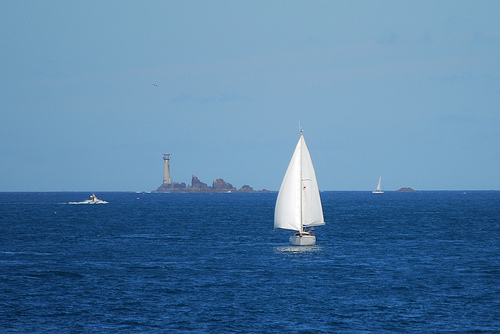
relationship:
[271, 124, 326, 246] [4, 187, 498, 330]
boat in water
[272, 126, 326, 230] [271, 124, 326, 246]
sail on boat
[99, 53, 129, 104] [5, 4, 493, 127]
white clouds in sky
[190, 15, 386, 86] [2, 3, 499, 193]
clouds in sky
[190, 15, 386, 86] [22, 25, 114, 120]
clouds in sky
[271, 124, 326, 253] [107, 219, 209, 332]
boat on water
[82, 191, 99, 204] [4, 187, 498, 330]
jetski on water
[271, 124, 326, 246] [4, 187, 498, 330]
boat on water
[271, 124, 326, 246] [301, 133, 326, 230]
boat has sail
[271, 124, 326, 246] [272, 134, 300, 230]
boat has sail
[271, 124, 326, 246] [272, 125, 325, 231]
boat has sail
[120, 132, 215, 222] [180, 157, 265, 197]
lighthouse on land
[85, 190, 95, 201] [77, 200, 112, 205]
person on jet ski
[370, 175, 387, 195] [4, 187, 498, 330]
sailboat on water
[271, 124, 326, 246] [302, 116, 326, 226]
boat has sail